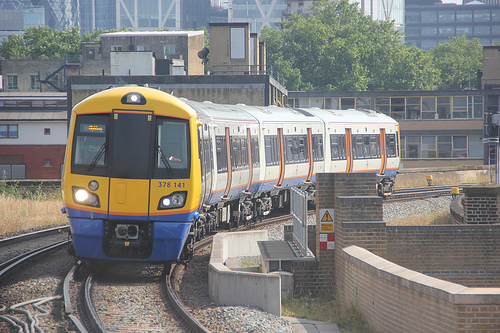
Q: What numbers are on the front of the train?
A: 378 141.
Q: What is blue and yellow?
A: Front of the train.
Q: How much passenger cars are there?
A: Four.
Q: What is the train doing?
A: Turning a corner.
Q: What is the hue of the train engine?
A: Blue and yellow.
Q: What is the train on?
A: Railroad tracks.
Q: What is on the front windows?
A: Windshield wipers.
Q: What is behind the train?
A: Buildings.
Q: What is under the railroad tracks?
A: Rocks.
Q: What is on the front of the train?
A: Headlights.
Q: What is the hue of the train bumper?
A: Blue.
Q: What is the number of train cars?
A: Four.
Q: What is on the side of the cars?
A: Doors.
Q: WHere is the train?
A: On the tracks.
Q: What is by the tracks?
A: A building.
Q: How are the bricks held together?
A: Mortar.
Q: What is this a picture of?
A: A train.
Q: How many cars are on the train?
A: Four.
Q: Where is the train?
A: On the tracks.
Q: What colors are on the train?
A: Yellow and blue.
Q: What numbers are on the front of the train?
A: 378141.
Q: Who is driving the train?
A: The conductor.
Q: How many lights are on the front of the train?
A: Three.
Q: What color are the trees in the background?
A: Green.